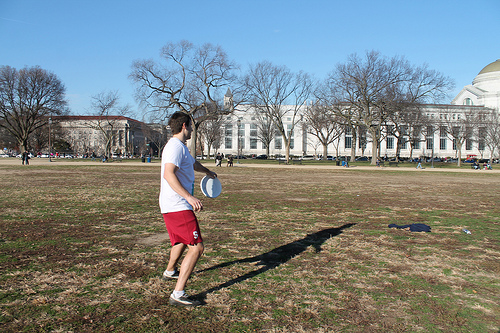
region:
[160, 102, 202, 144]
Person has brown hair.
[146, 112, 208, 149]
Person has short hair.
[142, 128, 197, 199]
Person wearing white shirt.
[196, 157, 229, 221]
Person holding white frisbee.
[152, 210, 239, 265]
Person wearing red shorts.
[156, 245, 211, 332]
Person wearing white socks.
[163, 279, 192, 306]
Person wearing dark shoes.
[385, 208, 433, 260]
Clothing laying in the grass.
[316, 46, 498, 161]
Large white building in distance.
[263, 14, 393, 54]
Sky is clear and blue.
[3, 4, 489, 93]
The sky is blue.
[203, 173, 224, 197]
The frisbee is white.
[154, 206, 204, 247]
The man is wearing red pants.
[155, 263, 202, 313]
His shoes are black.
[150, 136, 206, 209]
The man is wearing a white shirt.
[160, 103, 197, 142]
The man has brown hair.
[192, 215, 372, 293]
The man is casting a shadow.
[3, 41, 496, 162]
The trees are bare.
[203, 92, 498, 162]
The building is white.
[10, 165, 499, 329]
The ground is brown is green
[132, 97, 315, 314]
man throwing frisbee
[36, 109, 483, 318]
the man is in a park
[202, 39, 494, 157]
a building behind the park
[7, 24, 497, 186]
the trees are bare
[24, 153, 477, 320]
the grass is brown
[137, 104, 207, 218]
man wearing a white shirt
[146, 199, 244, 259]
man wearing red shorts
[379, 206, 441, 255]
a jacket on the ground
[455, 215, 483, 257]
a water bottle on the ground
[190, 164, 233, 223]
the frisbee is white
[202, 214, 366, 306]
shadow from man on ground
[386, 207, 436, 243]
a blue shirt on the ground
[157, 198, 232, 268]
Red shorts with white S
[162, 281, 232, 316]
Black and white shoes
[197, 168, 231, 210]
a white frisbee in hand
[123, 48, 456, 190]
trees with no leaves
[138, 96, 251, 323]
man holding a frisbee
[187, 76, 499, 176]
a long white building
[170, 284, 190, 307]
short white socks in shoes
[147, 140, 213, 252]
a white t-shirt and red shorts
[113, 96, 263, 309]
a man throwing a frisbee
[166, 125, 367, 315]
the man's shadow is on the ground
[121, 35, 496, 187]
the building behind the trees is white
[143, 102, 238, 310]
the man is wearing red shorts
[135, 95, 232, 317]
the man is wearing a white shirt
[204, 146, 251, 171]
a group of people are walking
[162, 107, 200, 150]
the man has short dark hair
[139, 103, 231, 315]
the man is wearing sneakers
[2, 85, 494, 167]
a smaller building next to the white building